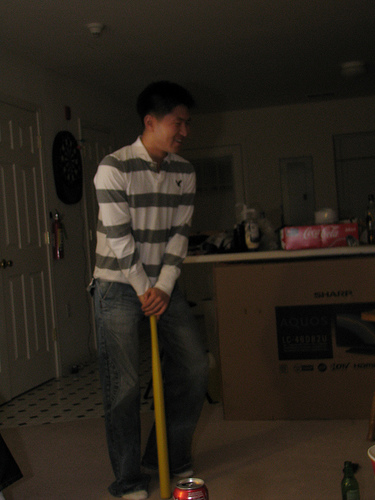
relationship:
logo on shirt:
[174, 178, 181, 187] [86, 136, 198, 298]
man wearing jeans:
[75, 75, 235, 498] [87, 280, 208, 499]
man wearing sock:
[75, 75, 235, 498] [173, 468, 194, 479]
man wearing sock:
[75, 75, 235, 498] [120, 488, 148, 498]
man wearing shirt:
[75, 75, 235, 498] [86, 136, 198, 298]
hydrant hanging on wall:
[50, 211, 67, 259] [42, 83, 91, 365]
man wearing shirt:
[75, 75, 235, 498] [92, 134, 225, 332]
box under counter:
[217, 259, 374, 411] [187, 233, 361, 265]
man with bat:
[75, 75, 235, 498] [119, 280, 190, 496]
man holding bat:
[75, 75, 235, 498] [144, 322, 178, 480]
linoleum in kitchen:
[19, 379, 104, 419] [0, 90, 363, 284]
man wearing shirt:
[75, 75, 235, 498] [96, 117, 204, 300]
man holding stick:
[75, 75, 235, 498] [148, 308, 173, 498]